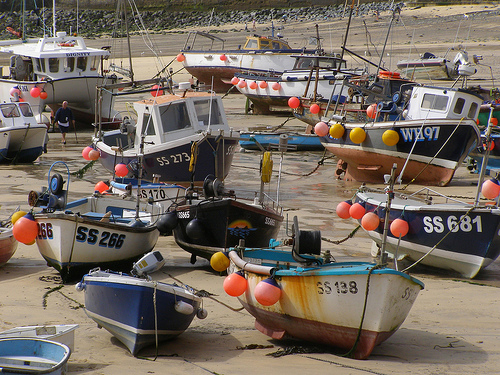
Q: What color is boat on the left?
A: Blue.